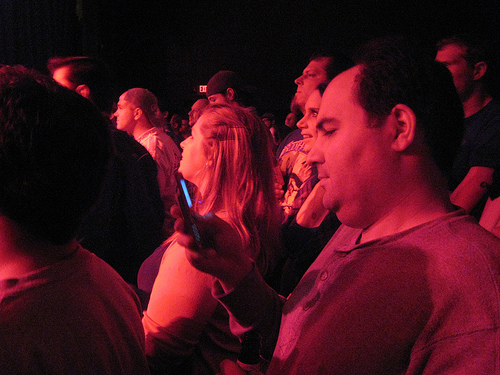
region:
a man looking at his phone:
[171, 48, 495, 373]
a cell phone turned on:
[173, 177, 203, 248]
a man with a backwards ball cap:
[203, 69, 260, 133]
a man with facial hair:
[263, 52, 349, 199]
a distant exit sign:
[195, 79, 208, 94]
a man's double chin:
[332, 200, 369, 235]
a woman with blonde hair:
[123, 97, 277, 374]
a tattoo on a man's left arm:
[475, 178, 490, 193]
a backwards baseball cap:
[114, 88, 167, 131]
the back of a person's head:
[0, 61, 131, 263]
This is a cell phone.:
[168, 169, 243, 287]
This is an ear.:
[378, 99, 447, 179]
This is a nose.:
[173, 135, 193, 150]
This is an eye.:
[305, 115, 355, 147]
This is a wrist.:
[194, 246, 281, 316]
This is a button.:
[296, 243, 362, 313]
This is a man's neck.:
[328, 177, 498, 259]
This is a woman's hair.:
[186, 89, 299, 292]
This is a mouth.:
[309, 165, 336, 187]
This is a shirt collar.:
[1, 230, 112, 318]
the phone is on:
[172, 170, 220, 258]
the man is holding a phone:
[170, 165, 454, 311]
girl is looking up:
[168, 101, 290, 236]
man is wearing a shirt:
[295, 235, 475, 347]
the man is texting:
[149, 110, 477, 335]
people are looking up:
[27, 38, 312, 228]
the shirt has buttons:
[303, 261, 353, 336]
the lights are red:
[54, 21, 486, 368]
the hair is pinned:
[219, 112, 257, 148]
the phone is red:
[159, 170, 215, 247]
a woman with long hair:
[174, 98, 287, 265]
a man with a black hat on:
[203, 61, 268, 116]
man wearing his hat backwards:
[204, 62, 268, 118]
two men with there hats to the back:
[102, 62, 259, 126]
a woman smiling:
[289, 75, 344, 168]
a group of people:
[14, 25, 486, 290]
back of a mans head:
[4, 63, 118, 273]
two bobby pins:
[217, 120, 250, 147]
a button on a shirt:
[314, 268, 331, 288]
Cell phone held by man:
[169, 176, 214, 258]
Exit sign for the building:
[195, 78, 213, 94]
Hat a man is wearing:
[204, 68, 249, 101]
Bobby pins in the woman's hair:
[215, 118, 245, 147]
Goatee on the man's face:
[289, 90, 303, 116]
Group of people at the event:
[4, 35, 499, 266]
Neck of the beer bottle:
[231, 323, 272, 374]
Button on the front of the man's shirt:
[299, 265, 348, 308]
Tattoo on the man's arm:
[478, 178, 495, 191]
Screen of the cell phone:
[178, 178, 195, 206]